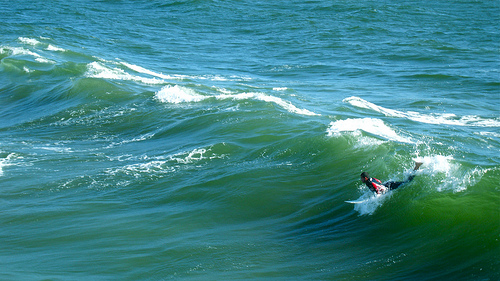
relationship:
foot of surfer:
[414, 160, 425, 169] [359, 161, 426, 194]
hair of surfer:
[360, 171, 371, 179] [359, 161, 426, 194]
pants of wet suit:
[384, 169, 417, 193] [368, 174, 416, 195]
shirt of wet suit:
[366, 177, 389, 193] [368, 174, 416, 195]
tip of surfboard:
[343, 198, 356, 207] [342, 178, 419, 206]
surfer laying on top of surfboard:
[359, 161, 426, 194] [342, 178, 419, 206]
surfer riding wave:
[359, 161, 426, 194] [201, 117, 499, 239]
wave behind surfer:
[201, 117, 499, 239] [359, 161, 426, 194]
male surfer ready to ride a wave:
[359, 161, 426, 194] [201, 117, 499, 239]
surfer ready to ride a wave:
[359, 161, 426, 194] [201, 117, 499, 239]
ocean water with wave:
[1, 1, 343, 280] [0, 35, 499, 239]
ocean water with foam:
[1, 1, 343, 280] [152, 84, 216, 105]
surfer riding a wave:
[359, 161, 426, 194] [201, 117, 499, 239]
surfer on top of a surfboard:
[359, 161, 426, 194] [342, 178, 419, 206]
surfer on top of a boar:
[359, 161, 426, 194] [342, 178, 419, 206]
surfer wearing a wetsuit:
[359, 161, 426, 194] [368, 174, 416, 195]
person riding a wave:
[359, 161, 426, 194] [201, 117, 499, 239]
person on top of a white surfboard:
[359, 161, 426, 194] [342, 178, 419, 206]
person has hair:
[359, 161, 426, 194] [360, 171, 371, 179]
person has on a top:
[359, 161, 426, 194] [366, 177, 389, 193]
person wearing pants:
[359, 161, 426, 194] [384, 169, 417, 193]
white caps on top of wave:
[4, 37, 205, 104] [0, 35, 499, 239]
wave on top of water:
[0, 35, 499, 239] [1, 1, 343, 280]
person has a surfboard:
[359, 161, 426, 194] [342, 178, 419, 206]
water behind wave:
[2, 1, 499, 36] [1, 32, 357, 182]